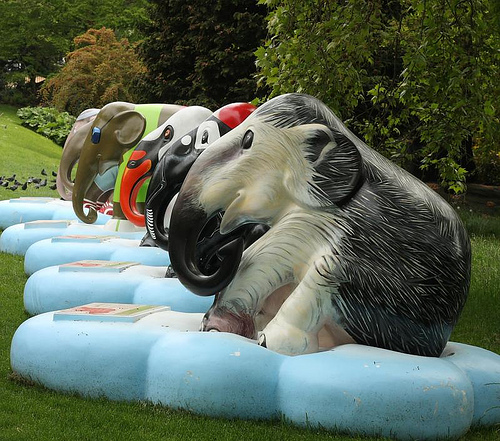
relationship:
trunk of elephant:
[167, 187, 244, 299] [166, 92, 471, 357]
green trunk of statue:
[74, 145, 96, 225] [64, 96, 183, 226]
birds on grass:
[2, 166, 63, 194] [0, 155, 64, 198]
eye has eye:
[229, 123, 274, 145] [239, 126, 254, 150]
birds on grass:
[0, 166, 63, 194] [0, 150, 64, 198]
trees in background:
[2, 2, 496, 189] [2, 0, 484, 193]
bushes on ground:
[16, 101, 78, 153] [4, 389, 154, 439]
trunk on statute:
[119, 142, 150, 223] [144, 103, 254, 246]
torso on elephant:
[122, 101, 162, 188] [81, 105, 138, 187]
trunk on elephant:
[174, 198, 244, 295] [166, 92, 471, 357]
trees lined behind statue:
[2, 2, 496, 189] [9, 92, 497, 436]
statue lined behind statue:
[9, 92, 497, 436] [23, 102, 255, 314]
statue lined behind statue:
[9, 92, 497, 436] [23, 103, 213, 276]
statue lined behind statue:
[9, 92, 497, 436] [0, 100, 186, 257]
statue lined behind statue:
[9, 92, 497, 436] [1, 107, 100, 231]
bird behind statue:
[20, 180, 28, 190] [73, 97, 180, 227]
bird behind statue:
[39, 165, 47, 176] [73, 97, 180, 227]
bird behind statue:
[49, 171, 58, 178] [73, 97, 180, 227]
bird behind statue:
[5, 183, 19, 195] [73, 97, 180, 227]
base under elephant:
[7, 305, 496, 421] [166, 92, 471, 357]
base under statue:
[16, 260, 214, 310] [145, 101, 260, 248]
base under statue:
[17, 230, 172, 268] [119, 106, 214, 223]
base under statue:
[0, 220, 144, 255] [70, 97, 202, 223]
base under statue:
[2, 195, 83, 225] [50, 102, 101, 196]